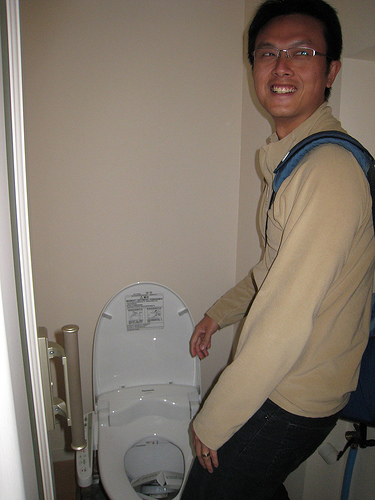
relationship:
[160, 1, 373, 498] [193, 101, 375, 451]
man standing in bathroom shirt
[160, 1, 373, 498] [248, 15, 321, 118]
man with face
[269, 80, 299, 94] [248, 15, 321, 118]
smile on face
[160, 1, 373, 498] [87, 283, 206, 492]
man standing in front of toilet